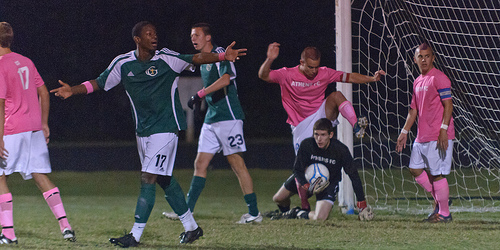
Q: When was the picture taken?
A: At night.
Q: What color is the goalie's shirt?
A: Black.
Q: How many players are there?
A: Six.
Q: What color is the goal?
A: White.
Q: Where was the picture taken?
A: The soccer field.